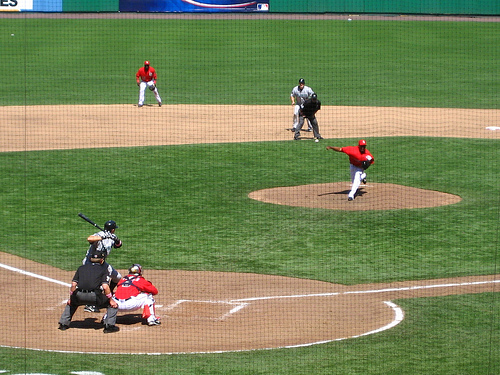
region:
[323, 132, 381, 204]
Pitcher delivers the pitch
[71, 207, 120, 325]
Batter anticipates pitch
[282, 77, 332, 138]
Runner watches action at plate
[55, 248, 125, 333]
Umpire prepares for the pitch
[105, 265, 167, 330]
Catcher gets ready for the pitch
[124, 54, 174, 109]
Shortstop stands at the ready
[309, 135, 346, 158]
Ball leaves pitcher's hand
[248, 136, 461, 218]
Pitcher delivers pitch from mound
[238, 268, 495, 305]
Basepath to first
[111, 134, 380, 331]
The battery of pitcher and catcher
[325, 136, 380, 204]
Pitcher on the mound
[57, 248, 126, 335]
An umpire behind home plate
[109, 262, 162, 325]
The catcher for the red team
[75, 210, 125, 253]
The batter up to bat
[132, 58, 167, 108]
The shortstop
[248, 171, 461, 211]
The pitching mound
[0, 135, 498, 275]
The infield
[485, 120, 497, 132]
Second base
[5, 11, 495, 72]
The outfield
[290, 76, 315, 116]
A runner that is well off of second base, trying to steal third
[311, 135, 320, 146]
Baseball in the air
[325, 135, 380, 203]
Baseball pitcher on pitcher mound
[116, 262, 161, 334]
Baseball catcher in ready position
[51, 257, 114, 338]
Umpire intensely watching for a ball or strike.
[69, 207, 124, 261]
Baseball batter ready for pitch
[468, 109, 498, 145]
Second base with no one on it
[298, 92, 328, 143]
Umpire between second and third base.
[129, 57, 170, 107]
Baseball shortstop player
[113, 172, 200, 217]
grass on a baseball field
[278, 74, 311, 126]
Baseball player from at bat team between second and third base.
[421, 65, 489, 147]
part of a meshed fence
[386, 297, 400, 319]
part of a white line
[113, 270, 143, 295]
part of a red top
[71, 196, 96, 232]
part of a club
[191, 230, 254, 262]
part of some grass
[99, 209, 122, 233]
part of a helmet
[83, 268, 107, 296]
part of a black top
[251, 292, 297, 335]
part of the ground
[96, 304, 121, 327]
part of a trouser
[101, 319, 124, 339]
part of a shoe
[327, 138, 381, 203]
man in red uniform pitching ball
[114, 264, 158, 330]
man in red uniform behind home plate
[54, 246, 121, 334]
man in umpire's uniform ssquatting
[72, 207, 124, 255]
man in white uniform holding bat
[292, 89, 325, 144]
man standing in front of man in white uniform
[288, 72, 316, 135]
man trying to steal third base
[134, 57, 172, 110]
man in red uniform defending the plate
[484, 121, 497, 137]
white base on tan field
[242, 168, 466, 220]
tan dirt of pitcher's mound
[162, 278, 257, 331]
white markings on home base